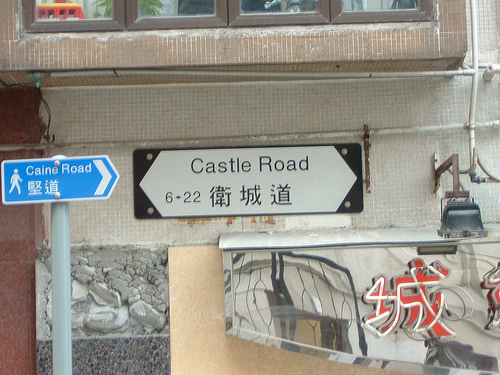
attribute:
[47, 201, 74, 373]
pole — grey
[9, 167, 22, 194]
person — walking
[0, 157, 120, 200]
sign — blue 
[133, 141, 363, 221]
sign — white , black 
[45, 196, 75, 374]
pole — metallic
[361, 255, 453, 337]
red sign — white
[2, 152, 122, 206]
sign — blue, white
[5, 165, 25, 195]
person — walking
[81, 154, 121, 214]
arrow — white 